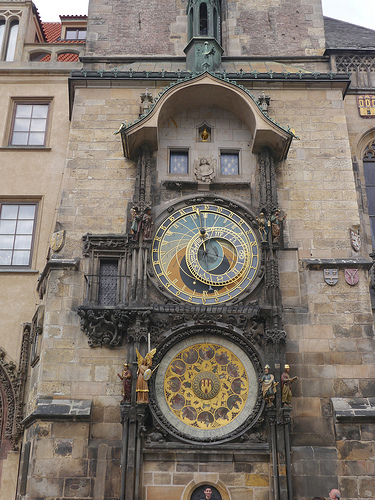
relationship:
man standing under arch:
[202, 487, 212, 500] [179, 469, 235, 500]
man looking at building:
[325, 488, 340, 500] [2, 2, 375, 500]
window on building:
[10, 101, 48, 142] [2, 2, 375, 500]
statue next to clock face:
[255, 203, 269, 245] [153, 201, 249, 290]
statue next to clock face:
[195, 151, 216, 189] [153, 201, 249, 290]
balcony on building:
[23, 41, 83, 64] [2, 2, 375, 500]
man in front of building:
[202, 487, 212, 500] [2, 2, 375, 500]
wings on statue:
[136, 348, 152, 372] [132, 344, 157, 398]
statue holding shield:
[132, 344, 157, 398] [145, 368, 153, 380]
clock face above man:
[153, 201, 249, 290] [202, 487, 212, 500]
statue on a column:
[259, 364, 279, 406] [265, 414, 301, 496]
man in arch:
[202, 487, 212, 500] [179, 469, 235, 500]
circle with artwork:
[147, 331, 269, 439] [164, 343, 247, 428]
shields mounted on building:
[320, 266, 360, 288] [2, 2, 375, 500]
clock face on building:
[153, 201, 249, 290] [2, 2, 375, 500]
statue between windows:
[195, 151, 216, 189] [168, 142, 240, 183]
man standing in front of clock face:
[202, 487, 212, 500] [153, 201, 249, 290]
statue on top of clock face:
[195, 151, 216, 189] [153, 201, 249, 290]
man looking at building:
[321, 488, 339, 500] [2, 2, 375, 500]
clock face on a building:
[153, 201, 249, 290] [2, 2, 375, 500]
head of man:
[203, 485, 216, 497] [202, 487, 212, 500]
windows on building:
[168, 142, 240, 183] [2, 2, 375, 500]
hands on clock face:
[190, 211, 211, 256] [153, 201, 249, 290]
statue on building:
[259, 364, 279, 406] [2, 2, 375, 500]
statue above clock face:
[195, 151, 216, 189] [153, 201, 249, 290]